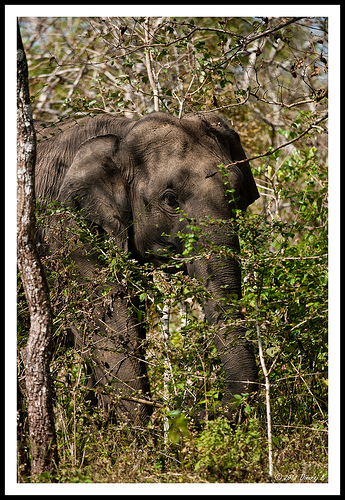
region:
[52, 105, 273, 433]
grey elephant in the wild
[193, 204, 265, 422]
long elephan trunk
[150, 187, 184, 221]
black eye of elephant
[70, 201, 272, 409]
twigs and branches behind elephant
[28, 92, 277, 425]
elephant walking through trees and bushes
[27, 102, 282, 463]
only one elephant in the picture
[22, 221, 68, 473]
skinny tree trunk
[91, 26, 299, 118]
branches with very few leaves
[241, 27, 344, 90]
blue sky seen through tree branches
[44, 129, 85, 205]
wrinkles on elephants grey skin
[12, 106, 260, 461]
grey big elephant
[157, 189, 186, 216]
eye of a grey elephant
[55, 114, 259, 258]
big ears of a grey elephant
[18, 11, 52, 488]
brown stem of a tree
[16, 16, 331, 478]
green bushes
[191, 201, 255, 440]
large grey trunk of an elephant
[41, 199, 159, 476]
branches covering the leg of the elephant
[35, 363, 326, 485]
branches in the ground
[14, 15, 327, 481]
picture of an elephant in the woods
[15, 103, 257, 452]
elephant between benchesin the wood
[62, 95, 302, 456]
There is one elephant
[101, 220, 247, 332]
this elephant does not have tusks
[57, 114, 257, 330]
elephant is in trees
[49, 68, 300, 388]
the elephant is in bushes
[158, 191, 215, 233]
the eye of the elephant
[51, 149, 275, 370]
the elephant is grey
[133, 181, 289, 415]
this is an elephant trunk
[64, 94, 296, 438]
the elephant is alone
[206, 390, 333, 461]
the leaves are green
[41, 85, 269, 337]
the elephant is in a forest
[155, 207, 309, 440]
the elephant has a long trunk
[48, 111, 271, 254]
the elephant has ears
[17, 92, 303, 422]
the elephant is gray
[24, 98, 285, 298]
the elephant has wrinkles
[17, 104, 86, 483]
the tree trunk is brown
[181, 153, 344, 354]
the bush is green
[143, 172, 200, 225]
the elephant has an eye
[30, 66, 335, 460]
the elephant is walking thorough bushes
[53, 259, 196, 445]
the elephant has legs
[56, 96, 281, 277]
the elephant has a head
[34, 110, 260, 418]
an elephant in the brush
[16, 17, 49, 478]
a tree next to an elephant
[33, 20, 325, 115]
branches above an elephants head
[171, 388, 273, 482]
leaves below an elephant's trunk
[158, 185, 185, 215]
an elephant's eye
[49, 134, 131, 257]
an elephant's ear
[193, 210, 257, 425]
an elephant's trunk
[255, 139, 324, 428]
brush to the side of an elephant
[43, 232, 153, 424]
an elephant's leg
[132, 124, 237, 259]
the face of an elephant